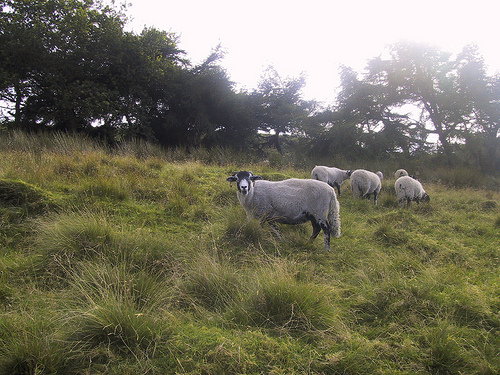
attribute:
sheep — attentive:
[232, 167, 343, 240]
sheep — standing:
[228, 170, 339, 250]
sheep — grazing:
[396, 175, 430, 210]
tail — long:
[327, 188, 349, 236]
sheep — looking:
[227, 169, 342, 256]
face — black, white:
[224, 167, 264, 197]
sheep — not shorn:
[232, 167, 347, 260]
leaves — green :
[265, 78, 320, 135]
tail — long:
[328, 187, 341, 237]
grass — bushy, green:
[273, 272, 453, 354]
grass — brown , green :
[38, 210, 237, 370]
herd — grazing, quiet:
[224, 162, 342, 245]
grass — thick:
[125, 255, 306, 354]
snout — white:
[221, 170, 266, 200]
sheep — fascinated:
[220, 153, 357, 277]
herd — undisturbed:
[224, 158, 439, 249]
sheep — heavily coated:
[223, 160, 434, 250]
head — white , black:
[226, 167, 258, 203]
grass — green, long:
[1, 126, 498, 373]